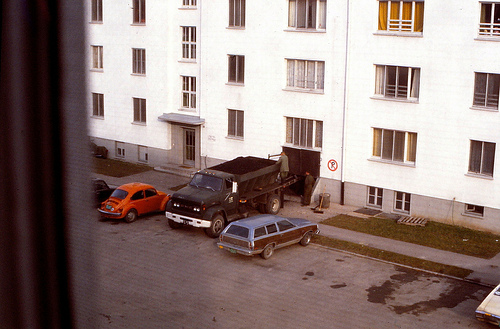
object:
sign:
[325, 158, 337, 171]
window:
[282, 57, 324, 92]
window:
[370, 63, 424, 104]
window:
[223, 52, 248, 86]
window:
[365, 124, 416, 167]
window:
[225, 106, 245, 142]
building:
[84, 0, 499, 235]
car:
[96, 181, 174, 222]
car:
[214, 213, 319, 259]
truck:
[164, 156, 299, 238]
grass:
[309, 213, 500, 278]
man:
[299, 169, 314, 207]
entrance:
[281, 146, 319, 197]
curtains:
[378, 0, 424, 32]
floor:
[93, 154, 499, 328]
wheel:
[261, 244, 276, 259]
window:
[277, 219, 296, 232]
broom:
[311, 183, 326, 214]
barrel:
[318, 191, 331, 208]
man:
[275, 151, 289, 186]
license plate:
[225, 246, 238, 254]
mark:
[363, 259, 484, 314]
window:
[282, 116, 324, 151]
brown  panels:
[253, 223, 318, 250]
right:
[468, 4, 500, 327]